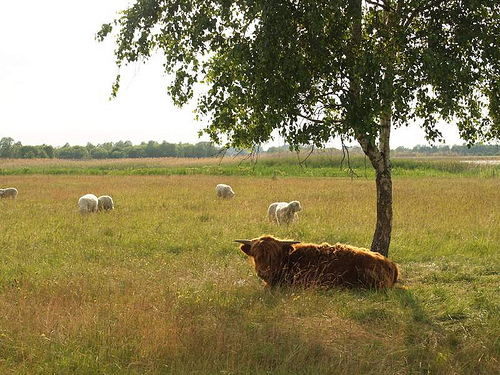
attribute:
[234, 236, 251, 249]
horn — straight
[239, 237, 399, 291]
bull — brown, taking shade, laying down, looking, large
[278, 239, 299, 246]
horn — straight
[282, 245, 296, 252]
ear — brown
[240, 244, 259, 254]
ear — brown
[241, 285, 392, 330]
grass — green, tall, tan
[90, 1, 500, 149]
leaves — green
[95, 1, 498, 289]
tree — giving shade, tall, close, in background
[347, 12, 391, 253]
trunk — brown, white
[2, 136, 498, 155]
trees — green, on horizon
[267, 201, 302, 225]
sheep — standing, grazing, white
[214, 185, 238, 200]
sheep — grazing, white, standing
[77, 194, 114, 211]
sheep — standing, grazing, white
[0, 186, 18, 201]
sheep — grazing, white, standing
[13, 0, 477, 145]
sky — gray, white, clear, bright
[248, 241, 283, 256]
fur — shaggy, brown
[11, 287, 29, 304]
flowers — yellow